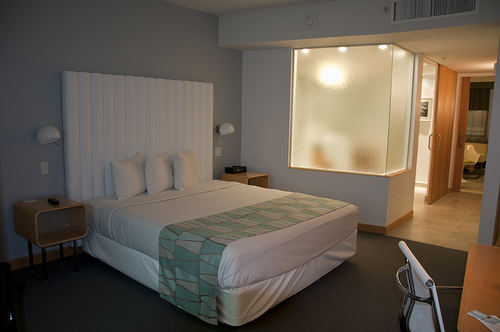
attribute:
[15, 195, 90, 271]
night stand — modern, wooden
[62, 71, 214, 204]
headboard — cushioned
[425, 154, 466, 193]
ground — tan, tiled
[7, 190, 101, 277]
table — night table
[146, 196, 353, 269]
blanket — colorful, throw blanket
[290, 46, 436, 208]
bathroom — clean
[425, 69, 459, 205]
door — brown, wooded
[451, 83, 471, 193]
door — wooded, brown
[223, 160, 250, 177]
stuff — black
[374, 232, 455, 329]
chair — white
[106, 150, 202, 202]
pillows — white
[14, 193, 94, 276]
night stand — modern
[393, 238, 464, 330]
chair — white, leather, office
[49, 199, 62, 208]
control — remote control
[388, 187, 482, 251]
flooring — tile, ceramic tile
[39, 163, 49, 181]
switch — wall switch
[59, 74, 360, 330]
bed — king sized